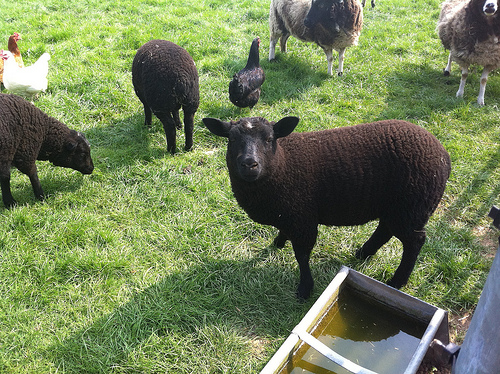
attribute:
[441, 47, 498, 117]
legs — white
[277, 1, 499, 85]
sheep — light colored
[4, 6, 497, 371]
grass field — long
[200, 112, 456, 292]
sheep — black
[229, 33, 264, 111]
chicken — black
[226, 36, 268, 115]
chicken — black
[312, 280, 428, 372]
water — murky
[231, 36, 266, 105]
chicken — black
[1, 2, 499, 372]
grass — green, lush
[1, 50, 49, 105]
chicken — white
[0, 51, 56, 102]
chicken — white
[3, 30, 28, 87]
chicken — red, yellow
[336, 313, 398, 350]
water — murky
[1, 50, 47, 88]
chicken — brown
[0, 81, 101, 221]
sheep — black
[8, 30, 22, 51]
head — red